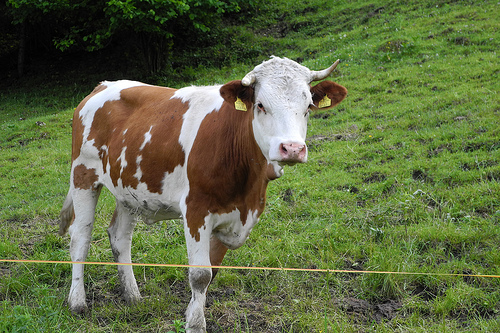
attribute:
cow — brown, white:
[53, 52, 374, 332]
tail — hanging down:
[47, 188, 76, 238]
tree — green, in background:
[2, 1, 88, 80]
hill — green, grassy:
[0, 0, 500, 331]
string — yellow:
[0, 255, 499, 286]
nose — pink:
[279, 141, 306, 163]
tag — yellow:
[232, 97, 249, 114]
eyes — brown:
[251, 101, 267, 114]